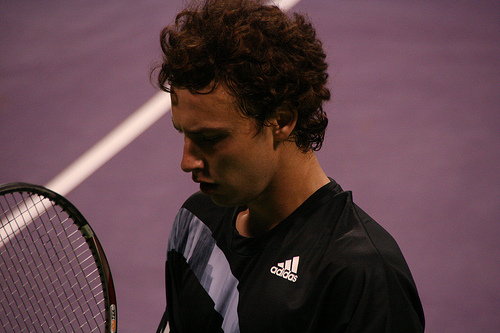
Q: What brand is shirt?
A: Adidas.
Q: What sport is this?
A: Tennis.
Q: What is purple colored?
A: Court.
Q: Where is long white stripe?
A: On court.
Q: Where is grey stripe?
A: On shirt.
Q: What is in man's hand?
A: Racket.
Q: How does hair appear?
A: Brown and curly.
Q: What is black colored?
A: Man's shirt.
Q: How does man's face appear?
A: Serious.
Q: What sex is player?
A: Male.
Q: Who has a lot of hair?
A: The man.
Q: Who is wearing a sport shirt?
A: The man.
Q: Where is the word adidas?
A: The shirt.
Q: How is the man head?
A: Tilted down.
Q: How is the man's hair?
A: Curly.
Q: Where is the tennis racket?
A: In front of the man.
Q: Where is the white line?
A: Next to the man.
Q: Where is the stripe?
A: On shirt.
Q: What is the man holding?
A: Racket.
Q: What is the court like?
A: Purple.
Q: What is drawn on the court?
A: Line.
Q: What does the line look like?
A: White paint.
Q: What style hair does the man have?
A: Brown and curly.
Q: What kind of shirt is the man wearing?
A: Adidas.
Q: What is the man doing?
A: Playing tennis.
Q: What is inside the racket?
A: Wire.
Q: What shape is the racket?
A: Circle.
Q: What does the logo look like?
A: White.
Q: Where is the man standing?
A: Tennis court.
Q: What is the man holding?
A: Tennis racket.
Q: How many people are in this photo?
A: One.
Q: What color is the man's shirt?
A: Black and white.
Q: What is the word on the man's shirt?
A: Adidas.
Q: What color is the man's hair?
A: Black.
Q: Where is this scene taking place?
A: Tennis court.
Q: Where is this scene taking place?
A: At the tennis match.